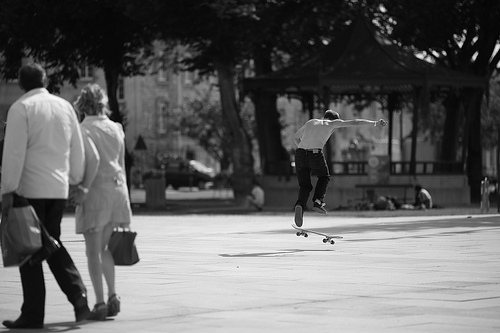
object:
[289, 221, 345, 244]
skateboard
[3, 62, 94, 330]
man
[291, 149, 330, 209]
black jeans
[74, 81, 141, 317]
woman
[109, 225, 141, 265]
bag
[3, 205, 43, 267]
bag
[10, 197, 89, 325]
pants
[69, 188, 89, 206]
hands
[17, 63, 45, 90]
hair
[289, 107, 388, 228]
man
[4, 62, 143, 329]
couple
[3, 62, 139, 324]
walking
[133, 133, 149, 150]
yield sign